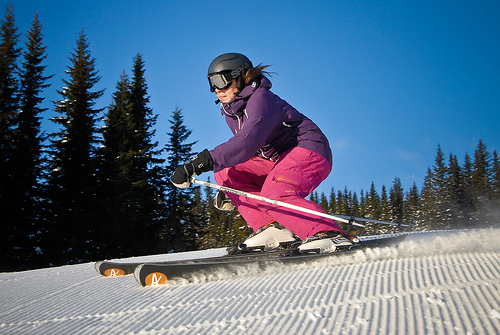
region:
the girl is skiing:
[97, 30, 472, 288]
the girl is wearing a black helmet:
[197, 51, 254, 73]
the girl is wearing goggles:
[197, 68, 268, 90]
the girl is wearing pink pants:
[211, 143, 337, 233]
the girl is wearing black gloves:
[169, 137, 212, 191]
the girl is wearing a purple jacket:
[202, 92, 336, 161]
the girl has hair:
[252, 56, 277, 82]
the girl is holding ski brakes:
[197, 29, 407, 248]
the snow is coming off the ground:
[358, 234, 496, 264]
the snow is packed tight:
[267, 282, 395, 315]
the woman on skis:
[118, 26, 411, 296]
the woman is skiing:
[73, 40, 461, 304]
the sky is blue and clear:
[339, 21, 439, 109]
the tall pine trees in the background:
[17, 57, 143, 235]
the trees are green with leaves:
[46, 70, 132, 218]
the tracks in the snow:
[250, 275, 463, 327]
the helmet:
[193, 47, 276, 103]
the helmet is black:
[192, 52, 285, 98]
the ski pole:
[167, 167, 397, 239]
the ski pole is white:
[163, 170, 366, 232]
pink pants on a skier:
[216, 152, 342, 248]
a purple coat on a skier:
[196, 86, 357, 171]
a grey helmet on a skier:
[201, 53, 259, 76]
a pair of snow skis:
[86, 234, 410, 288]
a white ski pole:
[157, 160, 368, 233]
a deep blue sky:
[0, 0, 495, 211]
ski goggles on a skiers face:
[200, 60, 246, 92]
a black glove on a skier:
[162, 145, 212, 190]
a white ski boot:
[233, 216, 296, 251]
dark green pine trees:
[101, 42, 154, 255]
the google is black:
[176, 58, 330, 143]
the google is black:
[186, 64, 260, 152]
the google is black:
[187, 35, 355, 270]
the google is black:
[209, 0, 297, 191]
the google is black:
[157, 2, 337, 167]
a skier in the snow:
[52, 32, 452, 333]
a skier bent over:
[34, 25, 496, 295]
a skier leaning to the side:
[61, 36, 463, 331]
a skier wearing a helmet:
[4, 6, 464, 333]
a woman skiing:
[78, 17, 445, 331]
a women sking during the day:
[11, 36, 441, 332]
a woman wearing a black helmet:
[76, 17, 454, 328]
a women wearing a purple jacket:
[80, 13, 496, 330]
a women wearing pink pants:
[114, 32, 418, 299]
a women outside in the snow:
[37, 11, 420, 312]